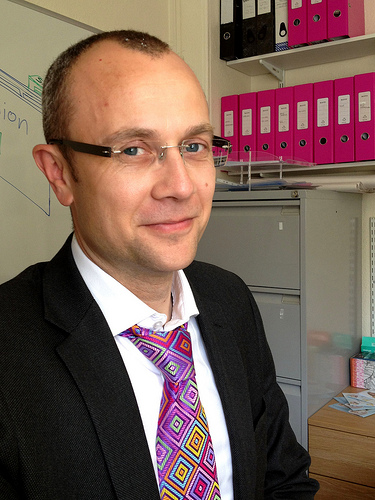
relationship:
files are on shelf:
[216, 69, 374, 166] [208, 61, 374, 175]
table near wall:
[302, 382, 373, 500] [181, 1, 374, 339]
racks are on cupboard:
[209, 146, 293, 191] [187, 182, 365, 480]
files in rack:
[213, 171, 312, 192] [209, 146, 293, 191]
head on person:
[32, 24, 222, 275] [2, 27, 323, 499]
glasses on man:
[43, 130, 235, 179] [2, 27, 323, 499]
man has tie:
[2, 27, 323, 499] [117, 321, 220, 499]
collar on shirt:
[65, 235, 205, 339] [62, 230, 237, 497]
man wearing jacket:
[2, 27, 323, 499] [0, 230, 318, 498]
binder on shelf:
[332, 74, 358, 166] [208, 61, 374, 175]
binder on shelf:
[352, 70, 375, 166] [208, 61, 374, 175]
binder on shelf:
[285, 0, 309, 50] [208, 61, 374, 175]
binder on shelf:
[308, 1, 327, 41] [208, 61, 374, 175]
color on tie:
[172, 332, 193, 361] [117, 321, 220, 499]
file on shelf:
[273, 0, 291, 50] [208, 61, 374, 175]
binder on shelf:
[313, 77, 336, 166] [224, 158, 374, 181]